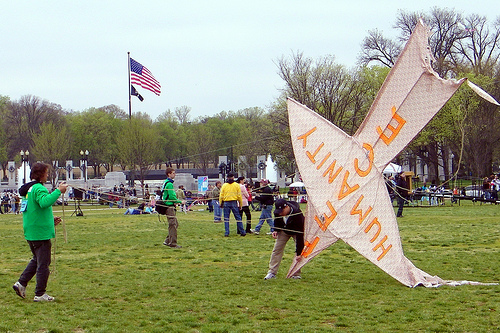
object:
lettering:
[296, 104, 406, 262]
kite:
[283, 19, 500, 289]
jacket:
[19, 181, 62, 241]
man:
[264, 199, 305, 280]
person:
[212, 181, 223, 223]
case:
[154, 200, 168, 213]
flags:
[127, 54, 162, 101]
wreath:
[258, 160, 268, 170]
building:
[1, 159, 304, 200]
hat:
[273, 200, 287, 215]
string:
[62, 78, 463, 245]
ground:
[0, 163, 500, 333]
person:
[237, 177, 254, 234]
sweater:
[237, 183, 249, 208]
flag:
[129, 60, 162, 94]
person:
[249, 179, 273, 235]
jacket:
[218, 182, 243, 207]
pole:
[127, 52, 133, 123]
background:
[0, 149, 499, 197]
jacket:
[270, 201, 305, 257]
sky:
[0, 1, 500, 116]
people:
[12, 162, 68, 299]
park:
[0, 6, 499, 333]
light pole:
[23, 149, 27, 185]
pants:
[17, 239, 53, 297]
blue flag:
[128, 56, 162, 103]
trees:
[0, 93, 44, 181]